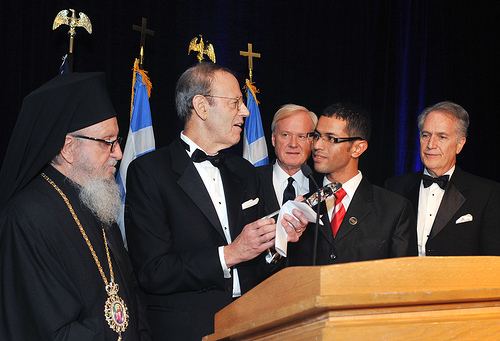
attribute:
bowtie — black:
[190, 146, 223, 168]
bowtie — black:
[419, 171, 452, 196]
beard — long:
[73, 148, 129, 231]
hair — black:
[320, 97, 373, 143]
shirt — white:
[178, 130, 243, 296]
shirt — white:
[406, 161, 460, 261]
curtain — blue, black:
[3, 1, 499, 204]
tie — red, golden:
[328, 188, 345, 242]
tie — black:
[281, 177, 301, 208]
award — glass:
[252, 174, 345, 268]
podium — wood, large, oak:
[195, 249, 498, 339]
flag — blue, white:
[115, 62, 163, 252]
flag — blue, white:
[241, 77, 273, 177]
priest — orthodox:
[3, 67, 153, 339]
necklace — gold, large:
[41, 165, 135, 340]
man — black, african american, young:
[277, 98, 419, 273]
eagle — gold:
[47, 5, 94, 37]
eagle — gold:
[182, 29, 217, 63]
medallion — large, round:
[101, 284, 133, 335]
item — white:
[266, 193, 328, 261]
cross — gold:
[235, 43, 264, 78]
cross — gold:
[127, 15, 160, 62]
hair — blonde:
[268, 99, 320, 136]